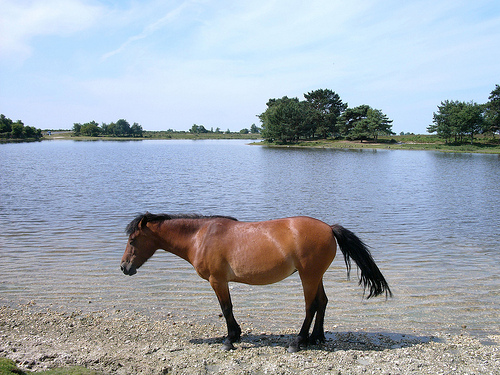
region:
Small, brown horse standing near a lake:
[117, 209, 395, 353]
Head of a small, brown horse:
[117, 208, 203, 278]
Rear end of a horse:
[285, 215, 392, 302]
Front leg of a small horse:
[196, 259, 245, 351]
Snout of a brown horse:
[117, 246, 146, 279]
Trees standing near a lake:
[256, 88, 321, 149]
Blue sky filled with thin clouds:
[42, 8, 212, 115]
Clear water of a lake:
[75, 146, 170, 196]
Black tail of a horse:
[327, 223, 395, 300]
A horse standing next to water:
[120, 211, 392, 349]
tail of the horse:
[339, 225, 396, 294]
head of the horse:
[109, 207, 164, 274]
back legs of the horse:
[295, 270, 323, 349]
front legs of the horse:
[198, 280, 241, 349]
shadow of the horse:
[241, 321, 421, 361]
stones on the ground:
[44, 298, 186, 361]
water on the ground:
[367, 207, 454, 265]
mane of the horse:
[135, 210, 240, 227]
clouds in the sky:
[192, 26, 342, 80]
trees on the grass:
[187, 123, 248, 134]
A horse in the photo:
[101, 190, 401, 347]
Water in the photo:
[165, 162, 264, 199]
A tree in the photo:
[231, 89, 408, 151]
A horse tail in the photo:
[327, 224, 398, 297]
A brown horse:
[112, 189, 405, 351]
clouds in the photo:
[173, 27, 285, 79]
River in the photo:
[64, 129, 129, 236]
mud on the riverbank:
[134, 332, 187, 364]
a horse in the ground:
[79, 183, 422, 373]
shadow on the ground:
[246, 322, 411, 359]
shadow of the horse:
[260, 304, 423, 354]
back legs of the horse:
[290, 303, 353, 352]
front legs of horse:
[212, 295, 259, 342]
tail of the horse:
[353, 230, 410, 323]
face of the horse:
[118, 210, 165, 271]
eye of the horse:
[126, 225, 154, 253]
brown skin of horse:
[175, 220, 227, 246]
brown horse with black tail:
[118, 211, 393, 353]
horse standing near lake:
[118, 157, 395, 359]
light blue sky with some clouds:
[19, 10, 299, 86]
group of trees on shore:
[255, 88, 400, 152]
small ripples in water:
[21, 265, 114, 303]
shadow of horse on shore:
[188, 322, 445, 354]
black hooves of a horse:
[219, 306, 327, 350]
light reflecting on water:
[375, 152, 449, 239]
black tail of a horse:
[330, 224, 395, 305]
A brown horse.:
[104, 203, 399, 353]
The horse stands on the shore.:
[103, 200, 400, 355]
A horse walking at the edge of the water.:
[93, 198, 412, 351]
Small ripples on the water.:
[18, 197, 115, 241]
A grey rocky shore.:
[22, 300, 493, 372]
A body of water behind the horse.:
[13, 130, 498, 297]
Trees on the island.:
[251, 90, 404, 149]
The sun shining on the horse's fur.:
[191, 210, 308, 292]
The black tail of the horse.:
[330, 222, 399, 307]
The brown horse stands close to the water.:
[117, 200, 392, 360]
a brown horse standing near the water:
[118, 211, 393, 352]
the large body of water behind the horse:
[1, 135, 499, 346]